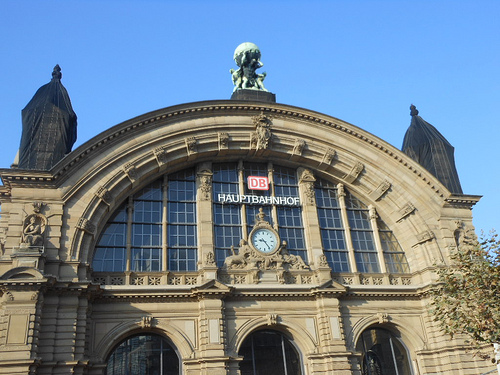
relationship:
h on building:
[217, 193, 226, 202] [1, 40, 497, 374]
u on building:
[231, 193, 241, 203] [1, 40, 497, 374]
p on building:
[241, 194, 246, 204] [1, 40, 497, 374]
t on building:
[246, 194, 253, 202] [1, 40, 497, 374]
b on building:
[253, 194, 260, 204] [1, 40, 497, 374]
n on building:
[275, 196, 282, 204] [1, 40, 497, 374]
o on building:
[287, 197, 294, 205] [1, 40, 497, 374]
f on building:
[293, 196, 301, 205] [1, 40, 497, 374]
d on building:
[250, 176, 258, 187] [1, 40, 497, 374]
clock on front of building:
[248, 224, 280, 256] [1, 40, 497, 374]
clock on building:
[248, 224, 280, 256] [1, 40, 497, 374]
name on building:
[215, 193, 300, 206] [1, 40, 497, 374]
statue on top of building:
[227, 40, 278, 101] [1, 40, 497, 374]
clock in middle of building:
[248, 224, 280, 256] [1, 40, 497, 374]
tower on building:
[396, 101, 465, 200] [1, 40, 497, 374]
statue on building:
[227, 40, 278, 101] [1, 40, 497, 374]